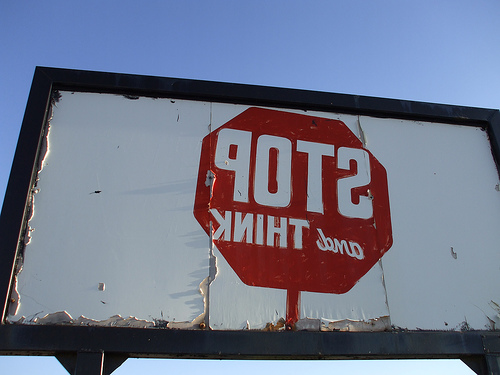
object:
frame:
[0, 59, 499, 375]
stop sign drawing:
[176, 95, 401, 331]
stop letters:
[211, 123, 379, 222]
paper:
[6, 86, 499, 342]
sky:
[0, 4, 500, 206]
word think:
[203, 205, 315, 254]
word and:
[310, 223, 368, 263]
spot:
[261, 315, 288, 335]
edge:
[338, 116, 386, 174]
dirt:
[87, 187, 104, 198]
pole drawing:
[284, 285, 304, 332]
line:
[199, 103, 220, 328]